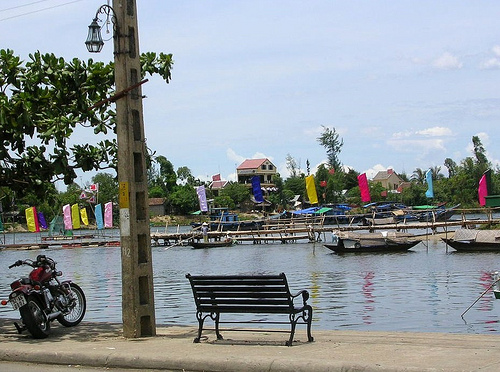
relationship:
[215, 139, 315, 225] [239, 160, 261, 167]
house has roof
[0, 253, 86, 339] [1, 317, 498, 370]
bike on concrete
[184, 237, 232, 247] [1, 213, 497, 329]
boat on water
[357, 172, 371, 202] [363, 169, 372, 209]
banner on pole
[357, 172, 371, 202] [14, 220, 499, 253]
banner on pier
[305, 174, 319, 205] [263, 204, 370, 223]
banner on pier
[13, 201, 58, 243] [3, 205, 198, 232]
flag on pier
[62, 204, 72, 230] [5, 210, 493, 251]
banner on pier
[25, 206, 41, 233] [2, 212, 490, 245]
flag on pier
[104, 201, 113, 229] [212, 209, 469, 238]
banner on pier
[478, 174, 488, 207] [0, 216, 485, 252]
banner on pier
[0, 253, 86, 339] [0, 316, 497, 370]
bike parked on sidewalk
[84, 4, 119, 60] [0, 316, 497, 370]
lamp by sidewalk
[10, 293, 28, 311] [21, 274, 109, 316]
license plate on bike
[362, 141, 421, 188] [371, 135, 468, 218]
roof on house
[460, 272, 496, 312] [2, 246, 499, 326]
stick in water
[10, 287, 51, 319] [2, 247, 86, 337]
license plate on bike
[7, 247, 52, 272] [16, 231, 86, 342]
bars on motorcycle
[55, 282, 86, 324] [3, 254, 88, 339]
tire on motorcyce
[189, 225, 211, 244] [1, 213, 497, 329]
man on water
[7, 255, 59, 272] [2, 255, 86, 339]
handle bars on bike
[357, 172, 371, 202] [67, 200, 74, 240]
banner on pole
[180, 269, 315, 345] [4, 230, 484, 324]
bench in area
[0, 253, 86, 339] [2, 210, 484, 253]
bike parked on dock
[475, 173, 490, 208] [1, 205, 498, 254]
banner on docking area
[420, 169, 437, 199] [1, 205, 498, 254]
banner on docking area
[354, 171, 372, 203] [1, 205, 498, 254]
banner on docking area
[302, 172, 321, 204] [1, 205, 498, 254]
banner on docking area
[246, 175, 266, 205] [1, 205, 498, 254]
banner on docking area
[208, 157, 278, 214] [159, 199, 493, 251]
house behind docking area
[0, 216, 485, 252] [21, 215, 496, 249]
pier on dock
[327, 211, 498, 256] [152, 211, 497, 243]
boats next to dock